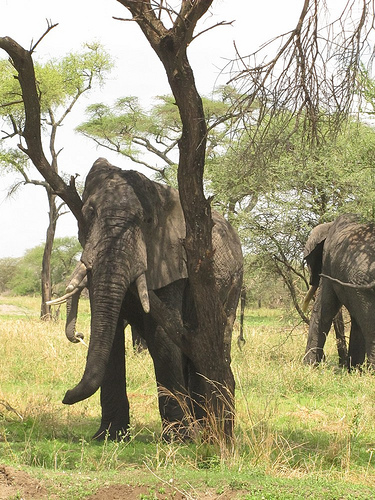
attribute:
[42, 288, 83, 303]
tusks — on elephant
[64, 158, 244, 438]
elephant — is large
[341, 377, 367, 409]
dried grass — on ground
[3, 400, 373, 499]
grass — dried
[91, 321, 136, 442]
leg — powerful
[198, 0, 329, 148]
branch — above, dried up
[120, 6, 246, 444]
tree — next to elephant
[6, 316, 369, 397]
grassy field — with elephants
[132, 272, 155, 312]
tusk — under tree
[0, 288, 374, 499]
grass — dried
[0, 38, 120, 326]
leaf — on tree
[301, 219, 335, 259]
ear — floppy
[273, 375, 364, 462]
grass — dried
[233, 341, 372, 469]
grass — dried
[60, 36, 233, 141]
branch — on tree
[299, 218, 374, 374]
elephant — facing away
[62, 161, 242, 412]
elephant — wrinkled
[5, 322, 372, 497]
grass — dried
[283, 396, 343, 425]
grass patch — dried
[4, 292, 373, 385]
grass — dried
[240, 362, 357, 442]
grass — dried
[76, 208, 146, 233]
eyes — dark, small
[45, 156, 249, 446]
elephant — relaxing, trunk, gray